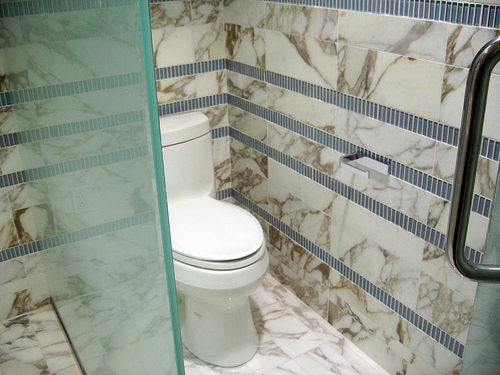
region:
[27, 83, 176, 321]
shower has glass walls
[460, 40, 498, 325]
handle on the shower door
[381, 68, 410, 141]
lines on the wall has stripes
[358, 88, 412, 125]
stripes are blue and white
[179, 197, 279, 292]
toilet seat is down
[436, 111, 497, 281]
shower handle is metal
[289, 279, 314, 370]
floor is tile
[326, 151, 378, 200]
toilet paper holder is stainless steel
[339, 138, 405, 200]
no toilet paper on the holder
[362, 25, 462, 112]
tile is white with brown swirls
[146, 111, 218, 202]
the tank is against the wall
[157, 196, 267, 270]
the toilet cove is down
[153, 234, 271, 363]
the toilet is on the floor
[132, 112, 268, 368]
the toilet is white in color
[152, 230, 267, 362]
the toilet bowl is made of ceramic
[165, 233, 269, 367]
the toilet bowl is shiny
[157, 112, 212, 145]
the tank cover is on top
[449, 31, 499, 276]
a handle is on the right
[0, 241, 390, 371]
the floor is made of tiles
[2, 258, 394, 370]
the tiles have a marble texture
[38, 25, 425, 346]
a bathroom scene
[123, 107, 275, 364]
a white toilet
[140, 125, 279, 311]
the toilet is clean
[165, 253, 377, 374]
a clean white marble floor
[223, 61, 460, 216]
blue tile on the wall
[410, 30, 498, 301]
a bar for handicapped people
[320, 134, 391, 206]
a toilet paper holder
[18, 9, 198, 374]
a glass divider wall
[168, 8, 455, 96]
brown and white marble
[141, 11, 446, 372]
small bathroom area for using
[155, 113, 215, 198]
a white porcelain toilet tank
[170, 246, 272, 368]
a white porcelain toilet bowl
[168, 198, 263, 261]
a white plastic toilet lid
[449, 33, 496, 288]
a chrome door handle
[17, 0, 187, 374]
a glass room divider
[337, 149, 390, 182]
a chrome toilet paper holder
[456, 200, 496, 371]
a glass door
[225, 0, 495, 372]
a marble tiled wall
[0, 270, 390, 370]
a marble tiled floor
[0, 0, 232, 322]
a marble tiled wall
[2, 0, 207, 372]
Glass divider in bathroom.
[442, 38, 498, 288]
Silver handle on door.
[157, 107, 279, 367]
White toilet in the bathroom.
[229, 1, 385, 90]
Brown and tan marbled tile.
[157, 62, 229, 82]
Blue tile on the wall.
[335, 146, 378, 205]
Silver toilet paper holder on wall.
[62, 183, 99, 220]
Plug in on wall.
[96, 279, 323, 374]
Tiled floor in the room.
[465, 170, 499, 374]
Glass door in the room.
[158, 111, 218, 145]
White top lid on toilet